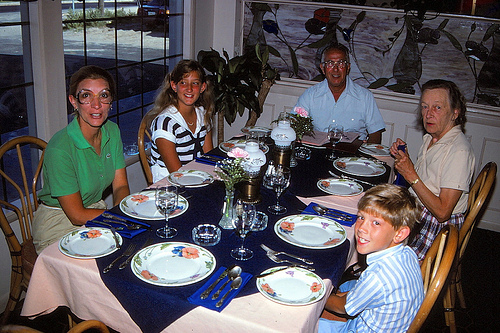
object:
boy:
[341, 183, 423, 332]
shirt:
[343, 241, 425, 333]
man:
[294, 45, 385, 146]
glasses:
[322, 59, 335, 69]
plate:
[132, 241, 216, 287]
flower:
[171, 245, 198, 260]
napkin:
[187, 263, 253, 312]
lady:
[37, 63, 131, 257]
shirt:
[38, 116, 127, 207]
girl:
[142, 59, 213, 188]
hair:
[177, 61, 199, 70]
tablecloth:
[18, 128, 400, 332]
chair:
[1, 135, 49, 323]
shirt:
[149, 101, 214, 167]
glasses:
[73, 89, 93, 104]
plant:
[191, 41, 281, 145]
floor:
[1, 225, 497, 332]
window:
[63, 1, 170, 105]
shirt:
[292, 78, 380, 141]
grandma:
[395, 77, 469, 265]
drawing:
[241, 1, 500, 109]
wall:
[161, 0, 500, 224]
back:
[2, 135, 47, 246]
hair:
[361, 186, 420, 221]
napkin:
[390, 142, 408, 160]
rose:
[226, 147, 249, 159]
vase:
[216, 178, 238, 228]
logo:
[105, 152, 112, 159]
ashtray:
[191, 222, 222, 246]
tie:
[188, 130, 206, 159]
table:
[40, 126, 397, 331]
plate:
[259, 267, 327, 305]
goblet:
[229, 201, 259, 260]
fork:
[261, 245, 315, 269]